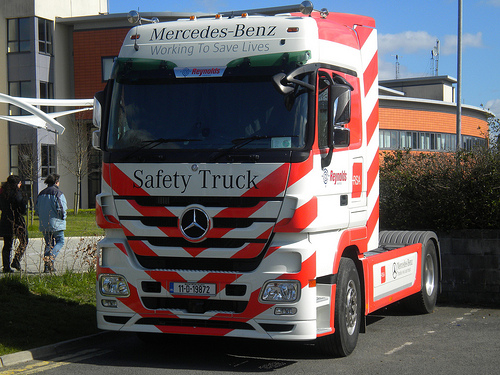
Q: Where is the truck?
A: Parking lot.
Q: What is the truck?
A: Safety truck.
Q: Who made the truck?
A: Mercedes.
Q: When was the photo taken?
A: Day time.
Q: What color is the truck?
A: Orange and white.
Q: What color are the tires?
A: Black.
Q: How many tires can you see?
A: Two.